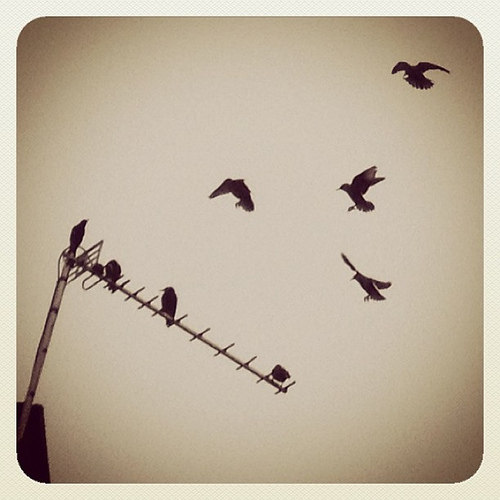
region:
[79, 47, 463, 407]
flock of black birds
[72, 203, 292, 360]
birds sitting on a pole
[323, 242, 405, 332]
bird with its wings spread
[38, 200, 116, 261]
bid perched on a pole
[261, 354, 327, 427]
bird sitting at the end of a pole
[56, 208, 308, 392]
five birds sitting together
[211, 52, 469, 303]
four birds flying together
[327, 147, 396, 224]
bird with wings in the air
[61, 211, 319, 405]
pole with lines across it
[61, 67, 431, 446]
cloudless sky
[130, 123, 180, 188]
part of the sly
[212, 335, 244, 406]
part of an aerial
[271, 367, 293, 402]
edge of an aerial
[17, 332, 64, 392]
part of a stand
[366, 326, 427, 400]
part of the sky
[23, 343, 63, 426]
part of a stand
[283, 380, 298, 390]
tip of the aerial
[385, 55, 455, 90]
Black bird flying highest in the sky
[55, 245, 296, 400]
Antenna birds are sitting on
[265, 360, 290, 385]
Bird sitting lowest on the antenna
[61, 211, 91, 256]
Blackbird sitting on antenna post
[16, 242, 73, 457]
Antenna attached to post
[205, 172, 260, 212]
Center black bird flying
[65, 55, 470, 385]
Flock of black birds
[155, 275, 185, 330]
Black bird sitting in the center of the antenna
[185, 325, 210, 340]
Bar attached to the antenna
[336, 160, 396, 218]
Black bird flapping his wings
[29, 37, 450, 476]
birds up in the air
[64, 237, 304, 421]
birds perched on metal wire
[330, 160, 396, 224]
bird flying ready to land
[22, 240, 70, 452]
pole where birds are resting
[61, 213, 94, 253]
bird perched on top of pole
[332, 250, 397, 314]
bird flying in mid air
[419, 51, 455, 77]
left wing of a bird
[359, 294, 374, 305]
claws of a bird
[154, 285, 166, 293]
beak of a bird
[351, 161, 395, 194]
wings of a bird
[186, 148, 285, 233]
bird in the sky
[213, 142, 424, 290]
three birds in the air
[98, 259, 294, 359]
birds on top of a metal thing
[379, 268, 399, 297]
wing of the bird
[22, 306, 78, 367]
pole under the birds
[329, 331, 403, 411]
white sky behind the birds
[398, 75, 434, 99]
tail feathers of the bird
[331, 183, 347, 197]
beak of the bird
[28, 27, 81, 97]
dark part of the photo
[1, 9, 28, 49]
white border of the photo